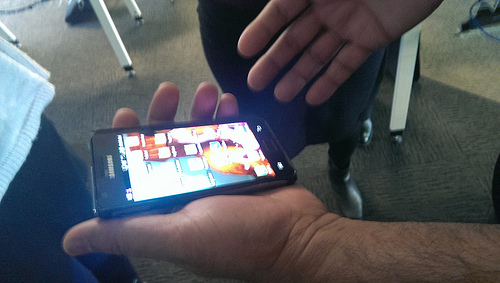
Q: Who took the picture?
A: A friend.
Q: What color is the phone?
A: Black.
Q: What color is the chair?
A: White.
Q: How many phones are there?
A: One.